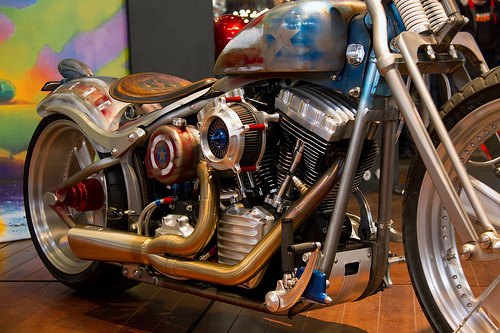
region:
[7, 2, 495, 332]
custom chopper motorcycle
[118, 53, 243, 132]
brown leather seat on chopper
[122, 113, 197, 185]
Captain America logo on motorcycle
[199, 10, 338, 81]
custom painted gas tank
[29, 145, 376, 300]
copper pipe on chopper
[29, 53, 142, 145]
custom paint on wheel cover of motorcycle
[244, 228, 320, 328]
foot peg on motorcycle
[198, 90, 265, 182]
air filter with red and blue parts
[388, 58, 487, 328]
front tire of chopper motorcycle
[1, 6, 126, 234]
colorful painting on wall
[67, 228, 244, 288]
Brass tubing on the motorcycle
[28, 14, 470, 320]
A heavily customized motorcycle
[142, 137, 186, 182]
Captain America logo on the bike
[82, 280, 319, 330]
Shadow of the motorcycle on the wooden floor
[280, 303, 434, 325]
A wooden floor beneath the bike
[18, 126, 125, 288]
A thick black tire on the bike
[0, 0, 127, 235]
A multicolored water painting behind the motorcycle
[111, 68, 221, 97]
A rusted bicycle seat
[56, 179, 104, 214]
A red joint on the tire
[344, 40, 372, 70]
A shiny metal bolt on the bike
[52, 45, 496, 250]
small toy motorcycle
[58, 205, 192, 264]
metal muffler of motorbike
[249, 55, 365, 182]
engine block of motorcycle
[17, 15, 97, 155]
green curtain behind bike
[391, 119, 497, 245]
front tire of motorcycle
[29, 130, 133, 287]
rear tire of motorcycle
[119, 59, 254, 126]
brown seat of motorcycle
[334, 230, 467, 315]
wooden floor under bike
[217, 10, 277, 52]
red object on shelf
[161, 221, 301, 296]
gold exhaust pipes on bike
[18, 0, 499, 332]
A red white and blue motorcycle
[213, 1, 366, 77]
A motorcycle gas tank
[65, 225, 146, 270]
A motorcycle exhaust pipe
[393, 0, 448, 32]
A pair of springs on the motorcycle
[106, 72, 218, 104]
A motorcycle seat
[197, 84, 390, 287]
A motorcycle engine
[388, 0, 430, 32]
A spring on a motorcycle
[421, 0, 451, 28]
A spring on a motorcycle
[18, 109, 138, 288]
A large motorcycle wheel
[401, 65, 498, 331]
A large motorcycle wheel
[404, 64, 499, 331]
The front wheel of the motorcycle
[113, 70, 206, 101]
The seat of the motorcycle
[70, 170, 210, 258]
Pipes on the motorcycle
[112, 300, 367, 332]
A shadow on the ground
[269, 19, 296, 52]
A star on the motorcycle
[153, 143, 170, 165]
A star on the side of the motorcycle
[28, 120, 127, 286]
The back wheel of the motorcycle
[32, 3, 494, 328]
A motorcycle with a patriotic design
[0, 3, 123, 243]
A painting behind the motorcycle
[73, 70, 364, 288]
The body of the motorcycle